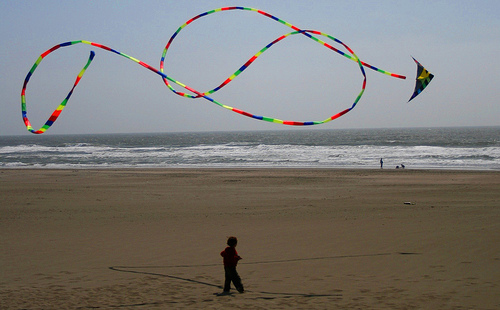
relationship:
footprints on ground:
[201, 292, 218, 303] [129, 269, 230, 307]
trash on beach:
[397, 199, 416, 210] [5, 166, 457, 230]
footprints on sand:
[201, 292, 218, 303] [320, 200, 401, 244]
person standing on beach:
[380, 158, 383, 166] [0, 166, 484, 308]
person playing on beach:
[394, 165, 400, 169] [0, 166, 484, 308]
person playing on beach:
[401, 164, 405, 168] [0, 166, 484, 308]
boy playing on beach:
[212, 231, 252, 302] [0, 166, 484, 308]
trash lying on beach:
[397, 199, 416, 210] [0, 166, 484, 308]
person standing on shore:
[378, 155, 384, 172] [0, 167, 484, 307]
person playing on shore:
[395, 166, 399, 169] [0, 167, 484, 307]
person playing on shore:
[401, 164, 405, 168] [0, 167, 484, 307]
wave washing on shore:
[3, 147, 500, 160] [0, 167, 484, 307]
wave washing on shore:
[3, 148, 484, 160] [0, 167, 484, 307]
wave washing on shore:
[2, 160, 251, 163] [0, 167, 484, 307]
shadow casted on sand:
[101, 235, 423, 294] [4, 167, 484, 301]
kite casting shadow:
[17, 5, 433, 134] [101, 235, 423, 294]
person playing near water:
[380, 158, 383, 166] [1, 127, 484, 173]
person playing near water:
[395, 166, 399, 169] [1, 127, 484, 173]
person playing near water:
[399, 161, 407, 168] [1, 127, 484, 173]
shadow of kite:
[101, 235, 423, 294] [17, 5, 433, 134]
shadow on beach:
[101, 235, 423, 294] [0, 166, 484, 308]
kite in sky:
[17, 5, 433, 134] [1, 2, 499, 134]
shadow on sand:
[101, 235, 423, 294] [4, 167, 484, 301]